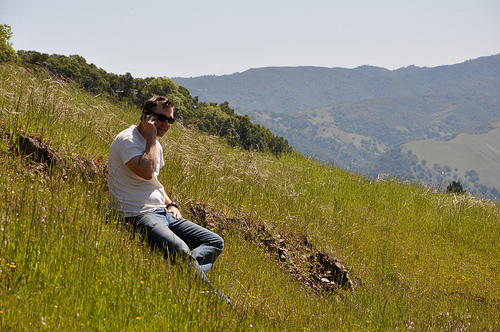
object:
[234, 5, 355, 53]
sky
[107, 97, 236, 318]
man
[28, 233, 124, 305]
grass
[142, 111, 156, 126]
phone